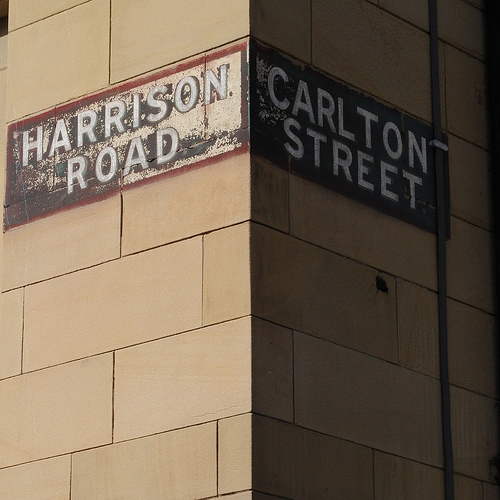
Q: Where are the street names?
A: On the side of the building.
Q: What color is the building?
A: It is brown.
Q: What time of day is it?
A: It is daytime.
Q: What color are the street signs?
A: They are red, white, and black.